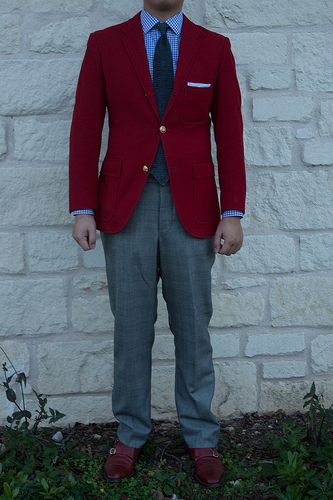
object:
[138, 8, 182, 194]
shirt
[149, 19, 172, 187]
tie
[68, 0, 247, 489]
man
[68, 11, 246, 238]
coat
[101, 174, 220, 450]
pants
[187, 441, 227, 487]
shoes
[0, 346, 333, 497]
vegetation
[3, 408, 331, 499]
ground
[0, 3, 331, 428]
wall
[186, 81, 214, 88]
card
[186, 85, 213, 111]
pocket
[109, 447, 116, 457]
buckles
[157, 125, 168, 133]
button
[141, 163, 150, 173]
button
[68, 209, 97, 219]
cuff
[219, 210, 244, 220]
cuff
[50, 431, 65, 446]
rock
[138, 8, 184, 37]
collar